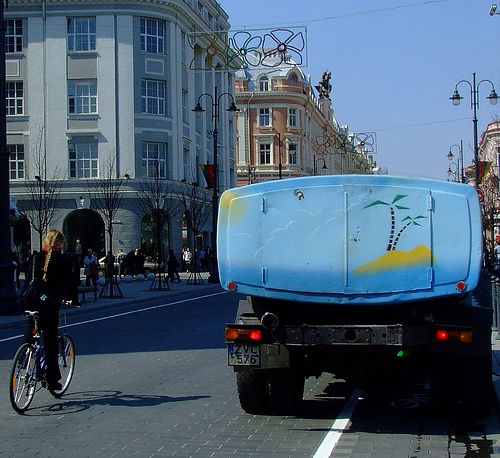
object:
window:
[67, 77, 98, 115]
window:
[68, 15, 96, 52]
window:
[138, 20, 163, 55]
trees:
[17, 131, 68, 252]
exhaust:
[261, 312, 279, 331]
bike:
[9, 299, 82, 414]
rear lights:
[225, 328, 239, 339]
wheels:
[266, 368, 304, 414]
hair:
[42, 229, 64, 281]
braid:
[42, 247, 52, 281]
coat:
[18, 251, 82, 307]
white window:
[3, 80, 23, 116]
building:
[1, 0, 245, 275]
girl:
[15, 229, 79, 391]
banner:
[199, 163, 215, 188]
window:
[256, 137, 273, 166]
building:
[234, 48, 382, 187]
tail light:
[436, 330, 449, 341]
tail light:
[459, 331, 472, 342]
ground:
[446, 153, 455, 161]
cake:
[447, 73, 499, 188]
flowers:
[187, 31, 228, 70]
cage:
[149, 272, 170, 291]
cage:
[98, 277, 123, 298]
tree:
[84, 152, 128, 299]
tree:
[129, 160, 183, 290]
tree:
[173, 171, 213, 285]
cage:
[186, 271, 204, 285]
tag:
[227, 343, 261, 367]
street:
[1, 271, 498, 453]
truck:
[216, 174, 494, 414]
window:
[66, 134, 99, 179]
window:
[141, 140, 167, 179]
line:
[314, 383, 367, 457]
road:
[6, 275, 259, 456]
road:
[2, 411, 492, 453]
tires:
[235, 369, 270, 415]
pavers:
[220, 416, 311, 453]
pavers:
[121, 405, 230, 452]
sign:
[259, 197, 441, 277]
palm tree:
[362, 194, 428, 251]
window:
[141, 78, 166, 116]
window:
[4, 17, 25, 53]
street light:
[446, 80, 499, 180]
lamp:
[486, 90, 499, 106]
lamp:
[448, 90, 463, 106]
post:
[211, 76, 218, 282]